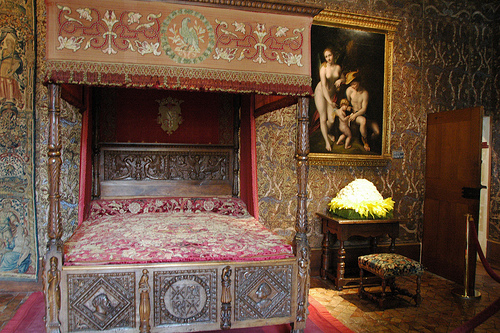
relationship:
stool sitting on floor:
[354, 251, 425, 311] [307, 260, 500, 331]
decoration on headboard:
[152, 93, 186, 136] [88, 83, 243, 200]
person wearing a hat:
[345, 72, 381, 151] [342, 67, 362, 85]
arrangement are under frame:
[326, 177, 397, 218] [297, 7, 402, 173]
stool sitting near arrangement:
[354, 251, 425, 311] [326, 177, 397, 218]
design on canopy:
[158, 9, 216, 63] [43, 2, 329, 102]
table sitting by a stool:
[316, 210, 400, 287] [354, 251, 425, 311]